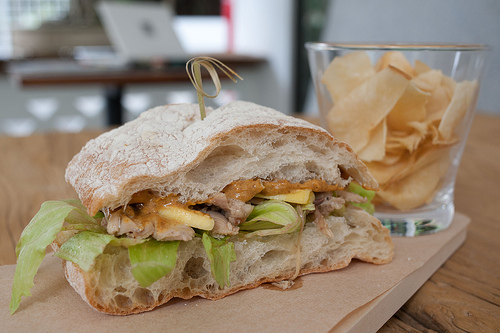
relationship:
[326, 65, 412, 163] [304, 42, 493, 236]
potato chips in glass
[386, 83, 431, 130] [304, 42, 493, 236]
potato chips in glass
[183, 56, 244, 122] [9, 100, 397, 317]
toothpick in sandwich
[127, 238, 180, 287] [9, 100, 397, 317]
lettuce on sandwich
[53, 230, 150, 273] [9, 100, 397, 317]
lettuce on sandwich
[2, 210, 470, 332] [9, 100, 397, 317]
paper under sandwich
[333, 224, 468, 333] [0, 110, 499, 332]
board on top of table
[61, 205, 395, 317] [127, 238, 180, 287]
bread under lettuce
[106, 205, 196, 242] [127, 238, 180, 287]
meat on lettuce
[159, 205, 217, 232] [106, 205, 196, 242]
cheese on meat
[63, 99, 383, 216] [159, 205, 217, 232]
bread on top of cheese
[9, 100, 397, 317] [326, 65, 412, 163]
sandwich next to potato chips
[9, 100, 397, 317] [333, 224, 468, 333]
sandwich on board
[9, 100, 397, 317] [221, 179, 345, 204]
sandwich has sauce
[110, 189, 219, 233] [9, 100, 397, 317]
sauce on sandwich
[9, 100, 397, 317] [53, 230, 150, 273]
sandwich has lettuce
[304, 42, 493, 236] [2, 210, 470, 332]
glass on top of paper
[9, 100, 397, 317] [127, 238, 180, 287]
sandwich has lettuce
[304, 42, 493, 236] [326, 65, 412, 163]
glass full of potato chips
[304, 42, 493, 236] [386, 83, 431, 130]
glass full of potato chips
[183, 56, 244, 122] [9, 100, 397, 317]
toothpick through sandwich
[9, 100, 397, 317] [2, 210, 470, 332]
sandwich on paper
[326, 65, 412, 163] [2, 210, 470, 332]
potato chips on paper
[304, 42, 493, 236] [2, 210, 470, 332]
glass on paper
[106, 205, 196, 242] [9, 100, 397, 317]
meat on sandwich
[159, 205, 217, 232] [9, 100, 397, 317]
cheese on sandwich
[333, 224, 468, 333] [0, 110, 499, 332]
board on table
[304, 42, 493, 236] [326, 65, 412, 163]
glass filled with potato chips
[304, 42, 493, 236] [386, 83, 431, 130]
glass filled with potato chips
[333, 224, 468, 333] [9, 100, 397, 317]
board under sandwich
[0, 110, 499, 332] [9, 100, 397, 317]
table under sandwich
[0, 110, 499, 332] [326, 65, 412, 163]
table under potato chips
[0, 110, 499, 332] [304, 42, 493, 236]
table under glass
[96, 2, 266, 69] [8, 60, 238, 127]
laptop on table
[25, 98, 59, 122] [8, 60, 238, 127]
light under table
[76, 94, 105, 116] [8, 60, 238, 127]
light under table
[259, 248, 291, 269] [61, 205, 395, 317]
hole in bread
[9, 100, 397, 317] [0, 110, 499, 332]
sandwich on table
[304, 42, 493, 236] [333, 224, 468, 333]
glass on board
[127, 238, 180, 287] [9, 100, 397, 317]
lettuce in sandwich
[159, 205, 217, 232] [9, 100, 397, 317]
cheese in sandwich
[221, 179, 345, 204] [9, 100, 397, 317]
sauce in sandwich